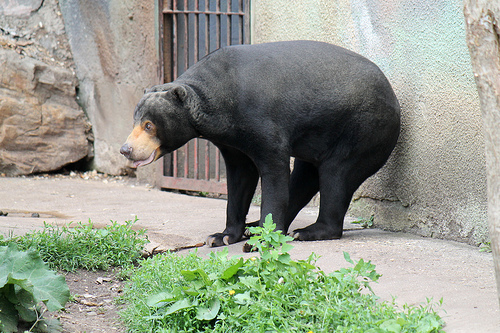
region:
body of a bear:
[288, 81, 299, 91]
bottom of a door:
[173, 177, 177, 187]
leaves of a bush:
[258, 274, 270, 316]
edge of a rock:
[71, 131, 81, 148]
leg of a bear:
[318, 137, 334, 200]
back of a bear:
[340, 70, 355, 77]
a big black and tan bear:
[121, 37, 411, 250]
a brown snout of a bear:
[119, 123, 160, 160]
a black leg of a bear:
[214, 141, 261, 243]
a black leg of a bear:
[252, 123, 293, 252]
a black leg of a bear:
[287, 149, 322, 241]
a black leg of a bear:
[290, 136, 362, 241]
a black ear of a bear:
[169, 83, 189, 103]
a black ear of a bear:
[143, 84, 158, 95]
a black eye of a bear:
[140, 122, 158, 132]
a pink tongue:
[131, 143, 158, 168]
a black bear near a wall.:
[102, 32, 405, 264]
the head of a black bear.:
[108, 75, 206, 175]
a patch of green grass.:
[85, 216, 468, 322]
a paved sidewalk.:
[3, 177, 496, 327]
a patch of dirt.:
[63, 262, 130, 332]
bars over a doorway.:
[160, 0, 257, 187]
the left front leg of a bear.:
[249, 124, 296, 242]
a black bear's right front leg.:
[203, 147, 266, 248]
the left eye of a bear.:
[139, 106, 163, 151]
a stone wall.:
[0, 0, 100, 182]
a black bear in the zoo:
[120, 40, 400, 245]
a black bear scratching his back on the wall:
[0, 0, 495, 330]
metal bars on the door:
[155, 0, 250, 40]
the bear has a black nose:
[117, 142, 128, 152]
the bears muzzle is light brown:
[122, 122, 157, 167]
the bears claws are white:
[206, 233, 241, 248]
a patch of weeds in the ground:
[0, 227, 436, 328]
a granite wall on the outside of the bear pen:
[1, 0, 119, 172]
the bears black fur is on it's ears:
[168, 84, 187, 106]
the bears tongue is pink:
[126, 156, 151, 170]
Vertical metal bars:
[152, 2, 259, 37]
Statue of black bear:
[96, 40, 391, 235]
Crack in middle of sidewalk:
[157, 240, 207, 253]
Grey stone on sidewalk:
[30, 206, 47, 222]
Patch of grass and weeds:
[147, 246, 347, 329]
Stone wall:
[10, 13, 94, 170]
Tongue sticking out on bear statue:
[123, 157, 153, 173]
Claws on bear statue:
[202, 232, 235, 248]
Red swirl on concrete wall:
[85, 6, 122, 86]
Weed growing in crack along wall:
[356, 211, 387, 233]